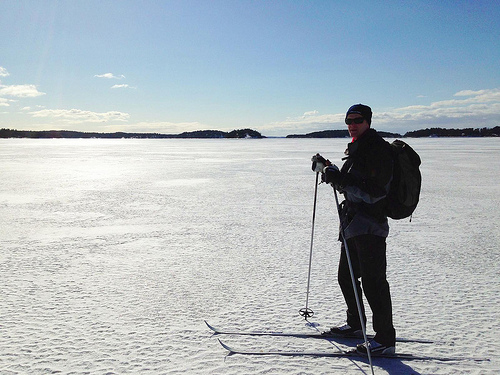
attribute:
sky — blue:
[67, 27, 426, 113]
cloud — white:
[81, 51, 135, 99]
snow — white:
[124, 138, 217, 192]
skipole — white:
[294, 163, 332, 328]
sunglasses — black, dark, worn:
[326, 111, 379, 131]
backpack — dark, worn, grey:
[389, 132, 429, 245]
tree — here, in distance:
[24, 109, 270, 144]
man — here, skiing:
[296, 80, 429, 336]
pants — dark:
[334, 228, 428, 352]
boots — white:
[332, 309, 414, 364]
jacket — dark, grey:
[299, 136, 411, 235]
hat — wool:
[338, 96, 377, 123]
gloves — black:
[295, 149, 340, 178]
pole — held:
[297, 159, 327, 310]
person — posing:
[289, 95, 446, 343]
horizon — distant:
[1, 119, 482, 152]